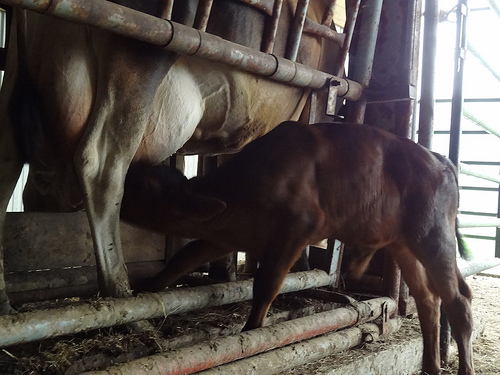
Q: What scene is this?
A: Barn.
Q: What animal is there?
A: Cow.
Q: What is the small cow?
A: Calf.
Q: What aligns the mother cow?
A: Gate.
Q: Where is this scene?
A: Barnhouse.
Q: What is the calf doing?
A: Drinking milk.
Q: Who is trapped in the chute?
A: Cow.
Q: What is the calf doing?
A: Drinking.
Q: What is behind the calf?
A: Metal gate.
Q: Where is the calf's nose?
A: Under the cow.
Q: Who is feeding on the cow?
A: Calf.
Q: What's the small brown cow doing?
A: Breastfeeding.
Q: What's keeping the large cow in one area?
A: Steel cage.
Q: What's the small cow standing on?
A: Four legs.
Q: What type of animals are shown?
A: Cows.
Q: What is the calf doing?
A: Nursing.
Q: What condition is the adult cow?
A: Standing.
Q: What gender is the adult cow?
A: Female.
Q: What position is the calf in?
A: Standing.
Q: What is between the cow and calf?
A: Fence.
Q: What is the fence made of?
A: Metal.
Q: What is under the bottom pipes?
A: Concrete.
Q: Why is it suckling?
A: Feeding.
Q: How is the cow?
A: Motionless.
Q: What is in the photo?
A: Cow.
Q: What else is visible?
A: Calf.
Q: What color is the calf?
A: Brown.